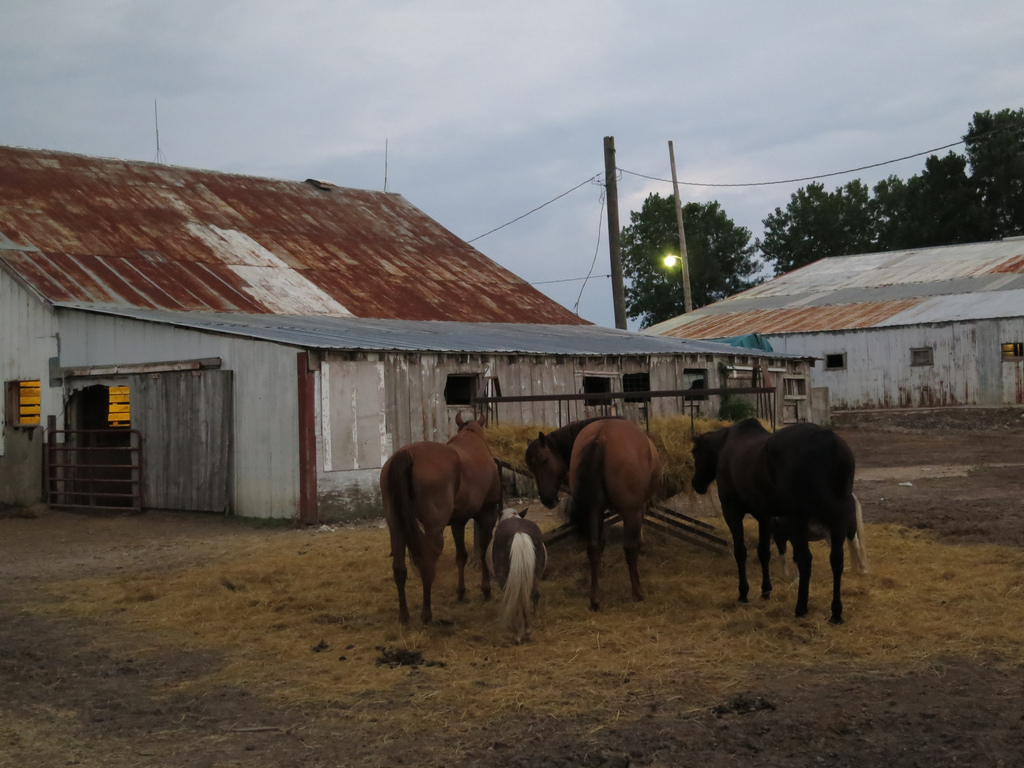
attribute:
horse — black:
[687, 418, 846, 624]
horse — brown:
[519, 411, 653, 620]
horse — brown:
[378, 412, 503, 619]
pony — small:
[488, 506, 534, 649]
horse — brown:
[364, 393, 500, 629]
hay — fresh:
[76, 523, 991, 676]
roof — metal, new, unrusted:
[71, 301, 812, 372]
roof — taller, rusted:
[7, 155, 586, 320]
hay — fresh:
[463, 396, 735, 495]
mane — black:
[512, 409, 627, 459]